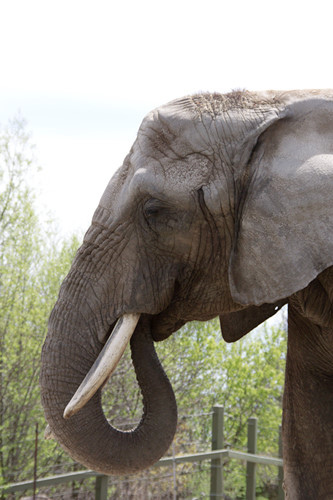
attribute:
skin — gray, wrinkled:
[58, 211, 125, 326]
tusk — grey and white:
[27, 314, 145, 431]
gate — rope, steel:
[166, 401, 238, 498]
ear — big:
[234, 106, 330, 292]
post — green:
[207, 402, 225, 498]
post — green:
[244, 415, 259, 499]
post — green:
[92, 470, 108, 498]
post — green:
[274, 422, 283, 499]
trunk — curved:
[40, 289, 178, 478]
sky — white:
[6, 0, 331, 198]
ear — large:
[225, 94, 332, 308]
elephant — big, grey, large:
[36, 85, 330, 497]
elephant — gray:
[17, 92, 330, 482]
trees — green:
[174, 336, 281, 435]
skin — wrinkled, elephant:
[85, 236, 155, 294]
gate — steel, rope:
[2, 403, 284, 498]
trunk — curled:
[40, 243, 176, 476]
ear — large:
[226, 96, 318, 305]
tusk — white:
[60, 311, 141, 419]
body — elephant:
[39, 86, 322, 498]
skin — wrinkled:
[175, 233, 235, 303]